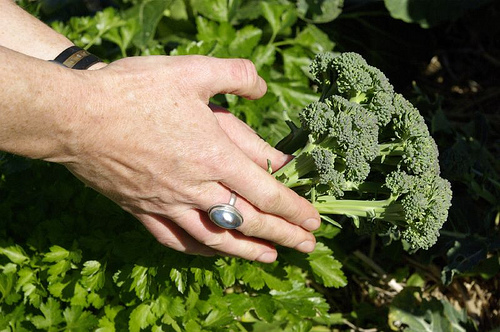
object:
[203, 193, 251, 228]
ring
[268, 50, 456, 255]
broccoli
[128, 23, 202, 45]
leaves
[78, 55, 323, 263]
hands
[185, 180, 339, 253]
finger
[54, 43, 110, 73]
watch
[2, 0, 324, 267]
person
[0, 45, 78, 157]
arm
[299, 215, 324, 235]
fingernails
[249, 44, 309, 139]
sunlight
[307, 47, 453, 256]
head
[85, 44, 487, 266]
picking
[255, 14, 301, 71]
leaf